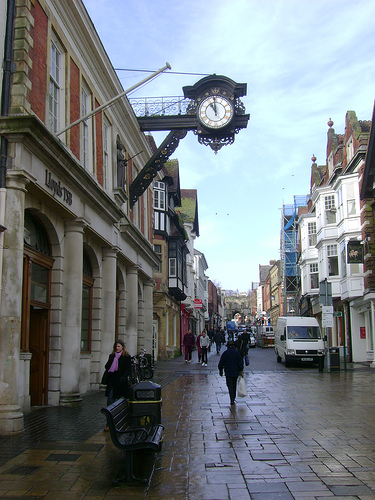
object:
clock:
[182, 73, 247, 142]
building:
[3, 4, 155, 437]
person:
[218, 340, 244, 405]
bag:
[237, 376, 247, 397]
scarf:
[108, 350, 124, 372]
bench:
[100, 397, 165, 484]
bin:
[127, 380, 163, 425]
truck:
[274, 315, 328, 371]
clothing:
[183, 333, 195, 360]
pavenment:
[2, 331, 374, 493]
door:
[28, 308, 49, 407]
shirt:
[200, 335, 210, 346]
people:
[182, 323, 251, 406]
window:
[116, 140, 128, 195]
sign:
[322, 305, 334, 327]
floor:
[290, 391, 362, 465]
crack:
[203, 461, 336, 500]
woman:
[101, 339, 132, 407]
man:
[183, 329, 196, 363]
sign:
[360, 327, 367, 339]